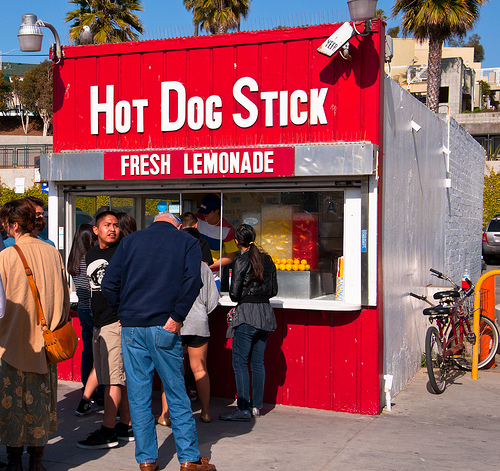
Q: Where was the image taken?
A: It was taken at the restaurant.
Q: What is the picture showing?
A: It is showing a restaurant.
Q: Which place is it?
A: It is a restaurant.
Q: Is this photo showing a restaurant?
A: Yes, it is showing a restaurant.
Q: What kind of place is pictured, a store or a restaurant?
A: It is a restaurant.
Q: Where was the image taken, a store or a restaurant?
A: It was taken at a restaurant.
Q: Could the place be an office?
A: No, it is a restaurant.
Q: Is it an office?
A: No, it is a restaurant.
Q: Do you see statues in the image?
A: No, there are no statues.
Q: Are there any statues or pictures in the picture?
A: No, there are no statues or pictures.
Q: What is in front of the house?
A: The tree is in front of the house.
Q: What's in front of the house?
A: The tree is in front of the house.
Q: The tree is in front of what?
A: The tree is in front of the house.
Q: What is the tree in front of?
A: The tree is in front of the house.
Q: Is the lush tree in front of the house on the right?
A: Yes, the tree is in front of the house.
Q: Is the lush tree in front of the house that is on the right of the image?
A: Yes, the tree is in front of the house.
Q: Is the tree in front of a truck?
A: No, the tree is in front of the house.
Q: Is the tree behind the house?
A: No, the tree is in front of the house.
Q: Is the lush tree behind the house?
A: No, the tree is in front of the house.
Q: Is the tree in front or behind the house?
A: The tree is in front of the house.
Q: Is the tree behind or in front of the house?
A: The tree is in front of the house.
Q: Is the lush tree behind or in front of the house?
A: The tree is in front of the house.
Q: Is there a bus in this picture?
A: No, there are no buses.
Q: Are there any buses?
A: No, there are no buses.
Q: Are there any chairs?
A: No, there are no chairs.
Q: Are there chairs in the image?
A: No, there are no chairs.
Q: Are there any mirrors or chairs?
A: No, there are no chairs or mirrors.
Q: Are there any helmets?
A: No, there are no helmets.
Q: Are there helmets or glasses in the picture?
A: No, there are no helmets or glasses.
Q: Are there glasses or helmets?
A: No, there are no helmets or glasses.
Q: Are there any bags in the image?
A: Yes, there is a bag.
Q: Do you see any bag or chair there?
A: Yes, there is a bag.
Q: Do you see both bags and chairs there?
A: No, there is a bag but no chairs.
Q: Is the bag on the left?
A: Yes, the bag is on the left of the image.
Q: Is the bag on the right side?
A: No, the bag is on the left of the image.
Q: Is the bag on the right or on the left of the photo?
A: The bag is on the left of the image.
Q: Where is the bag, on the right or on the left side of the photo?
A: The bag is on the left of the image.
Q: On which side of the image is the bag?
A: The bag is on the left of the image.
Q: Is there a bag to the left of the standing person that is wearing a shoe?
A: Yes, there is a bag to the left of the person.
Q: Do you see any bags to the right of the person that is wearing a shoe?
A: No, the bag is to the left of the person.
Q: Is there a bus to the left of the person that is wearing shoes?
A: No, there is a bag to the left of the person.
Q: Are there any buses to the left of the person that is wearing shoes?
A: No, there is a bag to the left of the person.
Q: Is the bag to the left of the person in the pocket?
A: Yes, the bag is to the left of the person.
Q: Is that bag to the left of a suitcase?
A: No, the bag is to the left of the person.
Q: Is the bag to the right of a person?
A: No, the bag is to the left of a person.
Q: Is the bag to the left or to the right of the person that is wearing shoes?
A: The bag is to the left of the person.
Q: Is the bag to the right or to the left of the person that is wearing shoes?
A: The bag is to the left of the person.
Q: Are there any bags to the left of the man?
A: Yes, there is a bag to the left of the man.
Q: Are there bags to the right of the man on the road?
A: No, the bag is to the left of the man.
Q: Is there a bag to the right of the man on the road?
A: No, the bag is to the left of the man.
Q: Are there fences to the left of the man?
A: No, there is a bag to the left of the man.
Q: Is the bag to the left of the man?
A: Yes, the bag is to the left of the man.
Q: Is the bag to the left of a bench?
A: No, the bag is to the left of the man.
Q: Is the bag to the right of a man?
A: No, the bag is to the left of a man.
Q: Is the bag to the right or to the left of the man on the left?
A: The bag is to the left of the man.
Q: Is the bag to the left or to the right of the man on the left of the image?
A: The bag is to the left of the man.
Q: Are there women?
A: Yes, there is a woman.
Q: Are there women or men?
A: Yes, there is a woman.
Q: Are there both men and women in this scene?
A: Yes, there are both a woman and a man.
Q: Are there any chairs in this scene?
A: No, there are no chairs.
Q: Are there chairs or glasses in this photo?
A: No, there are no chairs or glasses.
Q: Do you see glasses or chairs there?
A: No, there are no chairs or glasses.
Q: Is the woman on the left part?
A: Yes, the woman is on the left of the image.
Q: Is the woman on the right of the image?
A: No, the woman is on the left of the image.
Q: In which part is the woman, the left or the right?
A: The woman is on the left of the image.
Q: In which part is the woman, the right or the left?
A: The woman is on the left of the image.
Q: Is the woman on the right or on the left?
A: The woman is on the left of the image.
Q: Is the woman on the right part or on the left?
A: The woman is on the left of the image.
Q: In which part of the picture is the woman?
A: The woman is on the left of the image.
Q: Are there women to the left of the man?
A: Yes, there is a woman to the left of the man.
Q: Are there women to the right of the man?
A: No, the woman is to the left of the man.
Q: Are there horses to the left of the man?
A: No, there is a woman to the left of the man.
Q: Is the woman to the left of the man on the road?
A: Yes, the woman is to the left of the man.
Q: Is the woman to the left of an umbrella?
A: No, the woman is to the left of the man.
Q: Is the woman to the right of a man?
A: No, the woman is to the left of a man.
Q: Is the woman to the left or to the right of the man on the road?
A: The woman is to the left of the man.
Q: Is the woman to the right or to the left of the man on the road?
A: The woman is to the left of the man.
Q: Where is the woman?
A: The woman is on the road.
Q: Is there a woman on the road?
A: Yes, there is a woman on the road.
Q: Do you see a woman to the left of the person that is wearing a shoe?
A: Yes, there is a woman to the left of the person.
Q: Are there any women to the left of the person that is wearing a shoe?
A: Yes, there is a woman to the left of the person.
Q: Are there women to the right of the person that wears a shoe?
A: No, the woman is to the left of the person.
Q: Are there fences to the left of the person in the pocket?
A: No, there is a woman to the left of the person.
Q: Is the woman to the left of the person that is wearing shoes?
A: Yes, the woman is to the left of the person.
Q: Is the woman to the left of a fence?
A: No, the woman is to the left of the person.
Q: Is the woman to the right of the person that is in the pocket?
A: No, the woman is to the left of the person.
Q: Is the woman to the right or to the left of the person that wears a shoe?
A: The woman is to the left of the person.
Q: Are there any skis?
A: No, there are no skis.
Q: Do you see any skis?
A: No, there are no skis.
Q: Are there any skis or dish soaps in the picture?
A: No, there are no skis or dish soaps.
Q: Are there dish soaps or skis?
A: No, there are no skis or dish soaps.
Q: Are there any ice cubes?
A: No, there are no ice cubes.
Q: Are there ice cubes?
A: No, there are no ice cubes.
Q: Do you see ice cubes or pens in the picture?
A: No, there are no ice cubes or pens.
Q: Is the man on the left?
A: Yes, the man is on the left of the image.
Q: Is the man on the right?
A: No, the man is on the left of the image.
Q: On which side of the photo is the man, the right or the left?
A: The man is on the left of the image.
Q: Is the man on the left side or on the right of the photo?
A: The man is on the left of the image.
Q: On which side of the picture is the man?
A: The man is on the left of the image.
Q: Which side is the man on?
A: The man is on the left of the image.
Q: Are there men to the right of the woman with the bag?
A: Yes, there is a man to the right of the woman.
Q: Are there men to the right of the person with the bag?
A: Yes, there is a man to the right of the woman.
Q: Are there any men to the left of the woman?
A: No, the man is to the right of the woman.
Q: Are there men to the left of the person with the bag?
A: No, the man is to the right of the woman.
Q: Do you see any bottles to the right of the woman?
A: No, there is a man to the right of the woman.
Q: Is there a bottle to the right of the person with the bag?
A: No, there is a man to the right of the woman.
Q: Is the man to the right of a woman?
A: Yes, the man is to the right of a woman.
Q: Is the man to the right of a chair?
A: No, the man is to the right of a woman.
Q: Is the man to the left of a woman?
A: No, the man is to the right of a woman.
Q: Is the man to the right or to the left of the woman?
A: The man is to the right of the woman.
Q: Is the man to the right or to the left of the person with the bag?
A: The man is to the right of the woman.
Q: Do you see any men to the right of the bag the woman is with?
A: Yes, there is a man to the right of the bag.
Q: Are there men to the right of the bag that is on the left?
A: Yes, there is a man to the right of the bag.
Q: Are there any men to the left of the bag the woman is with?
A: No, the man is to the right of the bag.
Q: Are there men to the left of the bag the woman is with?
A: No, the man is to the right of the bag.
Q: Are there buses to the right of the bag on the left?
A: No, there is a man to the right of the bag.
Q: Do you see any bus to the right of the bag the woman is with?
A: No, there is a man to the right of the bag.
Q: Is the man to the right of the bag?
A: Yes, the man is to the right of the bag.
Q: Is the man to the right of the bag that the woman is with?
A: Yes, the man is to the right of the bag.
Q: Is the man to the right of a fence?
A: No, the man is to the right of the bag.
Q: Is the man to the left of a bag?
A: No, the man is to the right of a bag.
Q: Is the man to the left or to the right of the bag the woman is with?
A: The man is to the right of the bag.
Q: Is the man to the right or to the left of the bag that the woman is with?
A: The man is to the right of the bag.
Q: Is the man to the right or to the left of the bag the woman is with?
A: The man is to the right of the bag.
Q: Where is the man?
A: The man is on the road.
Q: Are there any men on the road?
A: Yes, there is a man on the road.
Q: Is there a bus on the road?
A: No, there is a man on the road.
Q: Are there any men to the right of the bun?
A: Yes, there is a man to the right of the bun.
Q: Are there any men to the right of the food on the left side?
A: Yes, there is a man to the right of the bun.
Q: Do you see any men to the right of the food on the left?
A: Yes, there is a man to the right of the bun.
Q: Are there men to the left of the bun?
A: No, the man is to the right of the bun.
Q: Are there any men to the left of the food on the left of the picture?
A: No, the man is to the right of the bun.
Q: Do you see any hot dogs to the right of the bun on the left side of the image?
A: No, there is a man to the right of the bun.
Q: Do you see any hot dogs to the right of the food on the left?
A: No, there is a man to the right of the bun.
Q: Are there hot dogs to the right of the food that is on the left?
A: No, there is a man to the right of the bun.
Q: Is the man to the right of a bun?
A: Yes, the man is to the right of a bun.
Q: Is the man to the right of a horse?
A: No, the man is to the right of a bun.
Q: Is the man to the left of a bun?
A: No, the man is to the right of a bun.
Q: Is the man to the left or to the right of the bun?
A: The man is to the right of the bun.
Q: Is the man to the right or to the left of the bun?
A: The man is to the right of the bun.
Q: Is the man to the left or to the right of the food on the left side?
A: The man is to the right of the bun.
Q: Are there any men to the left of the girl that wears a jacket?
A: Yes, there is a man to the left of the girl.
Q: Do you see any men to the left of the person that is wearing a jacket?
A: Yes, there is a man to the left of the girl.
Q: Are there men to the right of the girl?
A: No, the man is to the left of the girl.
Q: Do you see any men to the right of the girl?
A: No, the man is to the left of the girl.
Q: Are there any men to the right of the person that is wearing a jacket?
A: No, the man is to the left of the girl.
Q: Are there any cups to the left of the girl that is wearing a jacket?
A: No, there is a man to the left of the girl.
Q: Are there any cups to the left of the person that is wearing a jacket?
A: No, there is a man to the left of the girl.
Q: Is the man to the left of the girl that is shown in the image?
A: Yes, the man is to the left of the girl.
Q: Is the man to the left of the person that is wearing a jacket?
A: Yes, the man is to the left of the girl.